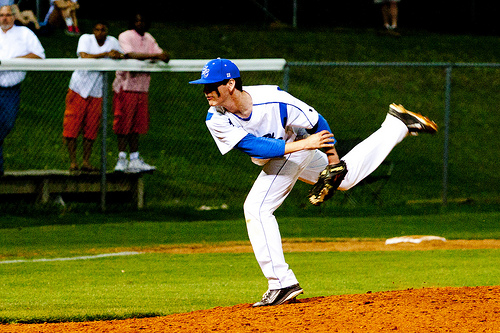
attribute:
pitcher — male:
[183, 55, 443, 310]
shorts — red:
[111, 86, 152, 139]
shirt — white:
[0, 27, 49, 88]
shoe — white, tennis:
[126, 154, 156, 174]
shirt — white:
[68, 34, 125, 102]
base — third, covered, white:
[382, 229, 450, 250]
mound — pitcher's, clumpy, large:
[0, 284, 500, 332]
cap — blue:
[185, 57, 247, 89]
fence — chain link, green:
[2, 56, 499, 224]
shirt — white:
[200, 87, 338, 166]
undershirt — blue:
[235, 112, 332, 162]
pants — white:
[240, 111, 415, 294]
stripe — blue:
[256, 155, 289, 291]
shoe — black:
[384, 96, 442, 140]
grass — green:
[2, 251, 500, 323]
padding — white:
[2, 56, 289, 76]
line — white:
[2, 241, 153, 271]